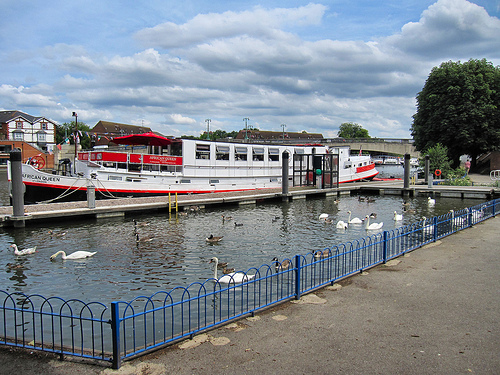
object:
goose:
[9, 244, 38, 257]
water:
[0, 190, 499, 352]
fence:
[1, 198, 500, 375]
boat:
[7, 138, 380, 195]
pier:
[0, 149, 500, 228]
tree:
[410, 57, 500, 173]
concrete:
[0, 213, 499, 375]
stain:
[271, 313, 287, 320]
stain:
[210, 336, 231, 346]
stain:
[383, 259, 402, 267]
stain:
[224, 323, 237, 328]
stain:
[180, 332, 211, 351]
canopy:
[109, 130, 173, 146]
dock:
[364, 184, 499, 199]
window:
[195, 144, 210, 160]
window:
[215, 145, 229, 161]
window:
[294, 148, 304, 161]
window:
[252, 147, 264, 161]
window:
[268, 148, 280, 161]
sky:
[0, 0, 499, 140]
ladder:
[168, 192, 178, 219]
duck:
[205, 234, 224, 243]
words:
[21, 173, 61, 182]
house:
[5, 114, 57, 153]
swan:
[50, 250, 98, 261]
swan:
[208, 257, 256, 284]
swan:
[449, 209, 464, 225]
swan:
[419, 216, 435, 234]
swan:
[346, 210, 362, 224]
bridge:
[0, 148, 499, 229]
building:
[89, 120, 155, 146]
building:
[234, 129, 325, 143]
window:
[39, 134, 46, 142]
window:
[14, 132, 24, 139]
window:
[41, 123, 47, 129]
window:
[39, 134, 45, 140]